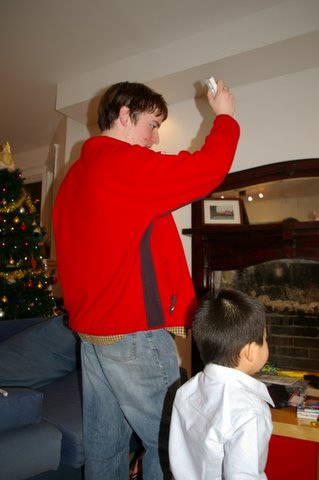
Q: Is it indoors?
A: Yes, it is indoors.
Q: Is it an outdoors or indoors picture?
A: It is indoors.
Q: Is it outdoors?
A: No, it is indoors.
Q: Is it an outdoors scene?
A: No, it is indoors.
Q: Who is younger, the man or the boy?
A: The boy is younger than the man.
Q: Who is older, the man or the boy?
A: The man is older than the boy.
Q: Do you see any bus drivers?
A: No, there are no bus drivers.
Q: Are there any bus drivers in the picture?
A: No, there are no bus drivers.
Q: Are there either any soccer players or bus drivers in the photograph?
A: No, there are no bus drivers or soccer players.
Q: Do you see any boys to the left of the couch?
A: No, the boy is to the right of the couch.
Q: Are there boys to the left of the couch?
A: No, the boy is to the right of the couch.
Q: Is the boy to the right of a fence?
A: No, the boy is to the right of the couch.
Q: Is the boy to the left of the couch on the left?
A: No, the boy is to the right of the couch.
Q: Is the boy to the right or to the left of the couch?
A: The boy is to the right of the couch.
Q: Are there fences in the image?
A: No, there are no fences.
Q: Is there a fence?
A: No, there are no fences.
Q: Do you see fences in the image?
A: No, there are no fences.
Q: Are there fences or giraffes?
A: No, there are no fences or giraffes.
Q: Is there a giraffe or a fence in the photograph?
A: No, there are no fences or giraffes.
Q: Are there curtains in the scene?
A: No, there are no curtains.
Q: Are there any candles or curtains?
A: No, there are no curtains or candles.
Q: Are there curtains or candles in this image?
A: No, there are no curtains or candles.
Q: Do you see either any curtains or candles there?
A: No, there are no curtains or candles.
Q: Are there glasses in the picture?
A: No, there are no glasses.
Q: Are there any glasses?
A: No, there are no glasses.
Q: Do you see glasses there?
A: No, there are no glasses.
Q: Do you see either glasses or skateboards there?
A: No, there are no glasses or skateboards.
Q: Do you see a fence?
A: No, there are no fences.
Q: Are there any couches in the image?
A: Yes, there is a couch.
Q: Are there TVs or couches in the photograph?
A: Yes, there is a couch.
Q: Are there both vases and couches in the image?
A: No, there is a couch but no vases.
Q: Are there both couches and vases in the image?
A: No, there is a couch but no vases.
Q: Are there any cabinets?
A: No, there are no cabinets.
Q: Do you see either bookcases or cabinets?
A: No, there are no cabinets or bookcases.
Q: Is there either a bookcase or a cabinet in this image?
A: No, there are no cabinets or bookcases.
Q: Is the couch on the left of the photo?
A: Yes, the couch is on the left of the image.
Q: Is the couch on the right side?
A: No, the couch is on the left of the image.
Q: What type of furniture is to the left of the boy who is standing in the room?
A: The piece of furniture is a couch.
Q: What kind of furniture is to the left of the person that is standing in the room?
A: The piece of furniture is a couch.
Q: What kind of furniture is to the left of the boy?
A: The piece of furniture is a couch.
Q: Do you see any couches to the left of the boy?
A: Yes, there is a couch to the left of the boy.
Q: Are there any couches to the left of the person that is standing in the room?
A: Yes, there is a couch to the left of the boy.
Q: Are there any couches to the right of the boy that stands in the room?
A: No, the couch is to the left of the boy.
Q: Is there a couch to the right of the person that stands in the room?
A: No, the couch is to the left of the boy.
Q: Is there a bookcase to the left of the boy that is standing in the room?
A: No, there is a couch to the left of the boy.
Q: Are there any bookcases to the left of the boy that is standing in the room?
A: No, there is a couch to the left of the boy.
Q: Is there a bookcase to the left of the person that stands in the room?
A: No, there is a couch to the left of the boy.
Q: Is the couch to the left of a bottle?
A: No, the couch is to the left of the boy.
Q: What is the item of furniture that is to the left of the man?
A: The piece of furniture is a couch.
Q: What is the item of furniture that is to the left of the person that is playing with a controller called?
A: The piece of furniture is a couch.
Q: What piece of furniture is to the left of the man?
A: The piece of furniture is a couch.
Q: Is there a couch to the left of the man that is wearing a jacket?
A: Yes, there is a couch to the left of the man.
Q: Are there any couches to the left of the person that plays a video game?
A: Yes, there is a couch to the left of the man.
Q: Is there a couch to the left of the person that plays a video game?
A: Yes, there is a couch to the left of the man.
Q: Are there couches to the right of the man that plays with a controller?
A: No, the couch is to the left of the man.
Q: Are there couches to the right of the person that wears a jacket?
A: No, the couch is to the left of the man.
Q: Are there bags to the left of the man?
A: No, there is a couch to the left of the man.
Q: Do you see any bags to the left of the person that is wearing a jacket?
A: No, there is a couch to the left of the man.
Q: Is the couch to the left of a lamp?
A: No, the couch is to the left of a man.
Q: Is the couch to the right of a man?
A: No, the couch is to the left of a man.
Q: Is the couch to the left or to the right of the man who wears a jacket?
A: The couch is to the left of the man.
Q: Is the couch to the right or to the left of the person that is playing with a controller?
A: The couch is to the left of the man.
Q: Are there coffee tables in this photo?
A: Yes, there is a coffee table.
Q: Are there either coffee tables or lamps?
A: Yes, there is a coffee table.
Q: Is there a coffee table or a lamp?
A: Yes, there is a coffee table.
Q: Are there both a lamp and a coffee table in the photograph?
A: No, there is a coffee table but no lamps.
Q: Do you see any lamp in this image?
A: No, there are no lamps.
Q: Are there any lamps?
A: No, there are no lamps.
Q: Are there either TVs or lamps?
A: No, there are no lamps or tvs.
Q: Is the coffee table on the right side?
A: Yes, the coffee table is on the right of the image.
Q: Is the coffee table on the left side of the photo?
A: No, the coffee table is on the right of the image.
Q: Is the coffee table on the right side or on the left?
A: The coffee table is on the right of the image.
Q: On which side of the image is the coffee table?
A: The coffee table is on the right of the image.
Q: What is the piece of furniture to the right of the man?
A: The piece of furniture is a coffee table.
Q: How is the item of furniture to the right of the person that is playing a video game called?
A: The piece of furniture is a coffee table.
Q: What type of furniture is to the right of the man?
A: The piece of furniture is a coffee table.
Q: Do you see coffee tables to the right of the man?
A: Yes, there is a coffee table to the right of the man.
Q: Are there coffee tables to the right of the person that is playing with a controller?
A: Yes, there is a coffee table to the right of the man.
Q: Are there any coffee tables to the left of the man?
A: No, the coffee table is to the right of the man.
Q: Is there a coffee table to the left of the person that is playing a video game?
A: No, the coffee table is to the right of the man.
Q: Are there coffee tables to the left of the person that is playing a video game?
A: No, the coffee table is to the right of the man.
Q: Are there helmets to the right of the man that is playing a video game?
A: No, there is a coffee table to the right of the man.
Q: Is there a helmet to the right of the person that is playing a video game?
A: No, there is a coffee table to the right of the man.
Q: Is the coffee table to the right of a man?
A: Yes, the coffee table is to the right of a man.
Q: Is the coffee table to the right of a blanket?
A: No, the coffee table is to the right of a man.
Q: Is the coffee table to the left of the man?
A: No, the coffee table is to the right of the man.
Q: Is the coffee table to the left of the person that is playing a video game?
A: No, the coffee table is to the right of the man.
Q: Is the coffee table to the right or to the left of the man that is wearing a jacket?
A: The coffee table is to the right of the man.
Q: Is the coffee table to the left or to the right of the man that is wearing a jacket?
A: The coffee table is to the right of the man.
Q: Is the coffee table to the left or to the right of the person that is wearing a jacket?
A: The coffee table is to the right of the man.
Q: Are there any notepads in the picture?
A: No, there are no notepads.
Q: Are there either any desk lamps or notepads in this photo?
A: No, there are no notepads or desk lamps.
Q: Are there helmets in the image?
A: No, there are no helmets.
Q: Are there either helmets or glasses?
A: No, there are no helmets or glasses.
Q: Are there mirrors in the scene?
A: Yes, there is a mirror.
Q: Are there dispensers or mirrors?
A: Yes, there is a mirror.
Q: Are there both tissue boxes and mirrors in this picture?
A: No, there is a mirror but no tissue boxes.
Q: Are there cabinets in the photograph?
A: No, there are no cabinets.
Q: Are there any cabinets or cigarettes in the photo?
A: No, there are no cabinets or cigarettes.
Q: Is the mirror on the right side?
A: Yes, the mirror is on the right of the image.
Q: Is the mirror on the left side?
A: No, the mirror is on the right of the image.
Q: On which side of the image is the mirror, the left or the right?
A: The mirror is on the right of the image.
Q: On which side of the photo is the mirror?
A: The mirror is on the right of the image.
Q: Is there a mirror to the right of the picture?
A: Yes, there is a mirror to the right of the picture.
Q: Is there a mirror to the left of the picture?
A: No, the mirror is to the right of the picture.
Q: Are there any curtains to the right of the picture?
A: No, there is a mirror to the right of the picture.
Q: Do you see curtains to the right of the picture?
A: No, there is a mirror to the right of the picture.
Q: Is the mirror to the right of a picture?
A: Yes, the mirror is to the right of a picture.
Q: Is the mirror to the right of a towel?
A: No, the mirror is to the right of a picture.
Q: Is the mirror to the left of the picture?
A: No, the mirror is to the right of the picture.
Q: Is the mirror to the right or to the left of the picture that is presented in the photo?
A: The mirror is to the right of the picture.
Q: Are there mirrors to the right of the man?
A: Yes, there is a mirror to the right of the man.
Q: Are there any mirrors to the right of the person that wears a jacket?
A: Yes, there is a mirror to the right of the man.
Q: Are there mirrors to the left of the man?
A: No, the mirror is to the right of the man.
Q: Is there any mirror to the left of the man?
A: No, the mirror is to the right of the man.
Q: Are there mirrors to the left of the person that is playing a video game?
A: No, the mirror is to the right of the man.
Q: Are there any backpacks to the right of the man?
A: No, there is a mirror to the right of the man.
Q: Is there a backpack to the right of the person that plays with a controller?
A: No, there is a mirror to the right of the man.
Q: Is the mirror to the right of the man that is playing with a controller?
A: Yes, the mirror is to the right of the man.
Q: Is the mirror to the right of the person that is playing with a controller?
A: Yes, the mirror is to the right of the man.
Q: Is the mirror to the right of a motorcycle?
A: No, the mirror is to the right of the man.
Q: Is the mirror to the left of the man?
A: No, the mirror is to the right of the man.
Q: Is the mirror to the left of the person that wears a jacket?
A: No, the mirror is to the right of the man.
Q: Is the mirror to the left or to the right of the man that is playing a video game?
A: The mirror is to the right of the man.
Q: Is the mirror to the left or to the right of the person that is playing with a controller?
A: The mirror is to the right of the man.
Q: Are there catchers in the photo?
A: No, there are no catchers.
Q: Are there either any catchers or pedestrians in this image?
A: No, there are no catchers or pedestrians.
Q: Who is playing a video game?
A: The man is playing a video game.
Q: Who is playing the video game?
A: The man is playing a video game.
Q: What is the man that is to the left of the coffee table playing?
A: The man is playing a video game.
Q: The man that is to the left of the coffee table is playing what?
A: The man is playing a video game.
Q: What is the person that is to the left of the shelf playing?
A: The man is playing a video game.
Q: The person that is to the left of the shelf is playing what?
A: The man is playing a video game.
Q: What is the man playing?
A: The man is playing a video game.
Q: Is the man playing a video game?
A: Yes, the man is playing a video game.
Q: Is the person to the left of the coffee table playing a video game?
A: Yes, the man is playing a video game.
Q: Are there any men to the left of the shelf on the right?
A: Yes, there is a man to the left of the shelf.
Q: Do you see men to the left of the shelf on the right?
A: Yes, there is a man to the left of the shelf.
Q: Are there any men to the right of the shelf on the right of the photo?
A: No, the man is to the left of the shelf.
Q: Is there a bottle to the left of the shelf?
A: No, there is a man to the left of the shelf.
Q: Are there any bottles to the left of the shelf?
A: No, there is a man to the left of the shelf.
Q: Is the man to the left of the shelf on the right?
A: Yes, the man is to the left of the shelf.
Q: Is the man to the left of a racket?
A: No, the man is to the left of the shelf.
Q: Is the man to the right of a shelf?
A: No, the man is to the left of a shelf.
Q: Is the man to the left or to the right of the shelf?
A: The man is to the left of the shelf.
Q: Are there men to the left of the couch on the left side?
A: No, the man is to the right of the couch.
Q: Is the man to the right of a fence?
A: No, the man is to the right of the couch.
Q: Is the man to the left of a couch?
A: No, the man is to the right of a couch.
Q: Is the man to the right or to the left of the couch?
A: The man is to the right of the couch.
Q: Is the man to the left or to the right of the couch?
A: The man is to the right of the couch.